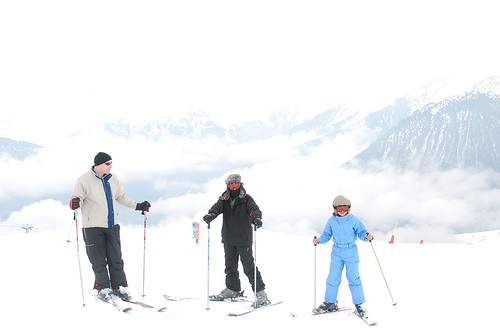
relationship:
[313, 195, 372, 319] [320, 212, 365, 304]
kid has outfit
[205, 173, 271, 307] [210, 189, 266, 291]
skier has outfit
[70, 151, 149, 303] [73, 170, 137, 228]
man has coat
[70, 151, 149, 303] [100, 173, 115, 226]
man has shirt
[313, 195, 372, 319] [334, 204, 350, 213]
kid has goggles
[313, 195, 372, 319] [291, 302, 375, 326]
kid has skis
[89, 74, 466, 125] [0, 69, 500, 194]
snow covering mountains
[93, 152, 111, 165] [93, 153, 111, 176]
hat on head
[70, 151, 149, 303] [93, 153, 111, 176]
man has head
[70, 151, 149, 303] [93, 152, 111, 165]
man wearing hat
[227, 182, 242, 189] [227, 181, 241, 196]
goggles on face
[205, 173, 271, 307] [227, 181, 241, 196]
skier has face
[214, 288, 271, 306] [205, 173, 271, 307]
boots on skier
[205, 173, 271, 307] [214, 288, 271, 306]
skier wearing boots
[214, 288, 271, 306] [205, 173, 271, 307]
boots strapped onto skier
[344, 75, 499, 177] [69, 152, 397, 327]
mountain behind group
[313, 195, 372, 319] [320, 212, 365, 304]
kid wearing outfit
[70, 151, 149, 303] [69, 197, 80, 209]
man wearing glove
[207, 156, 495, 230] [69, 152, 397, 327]
cloud behind group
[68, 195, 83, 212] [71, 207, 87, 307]
hand holding pole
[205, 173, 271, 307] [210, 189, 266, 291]
skier wearing outfit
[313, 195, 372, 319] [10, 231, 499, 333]
kid standing in snow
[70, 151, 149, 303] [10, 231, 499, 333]
man standing in snow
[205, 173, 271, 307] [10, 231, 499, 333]
skier standing in snow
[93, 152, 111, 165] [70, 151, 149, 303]
hat on man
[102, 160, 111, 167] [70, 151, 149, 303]
sunglasses resting on man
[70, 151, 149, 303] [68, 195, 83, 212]
man has hand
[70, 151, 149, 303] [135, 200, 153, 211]
man has hand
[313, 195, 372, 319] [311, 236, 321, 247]
kid has hand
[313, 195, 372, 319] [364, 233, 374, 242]
kid has hand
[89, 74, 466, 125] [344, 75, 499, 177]
snow covering mountain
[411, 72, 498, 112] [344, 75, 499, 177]
snow on mountain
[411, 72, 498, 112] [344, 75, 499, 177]
snow covering mountain